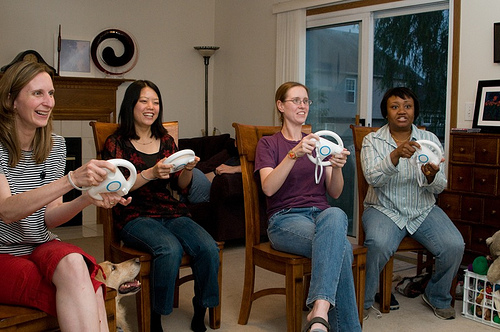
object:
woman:
[2, 59, 111, 332]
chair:
[88, 119, 228, 332]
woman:
[103, 77, 219, 332]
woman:
[256, 81, 363, 332]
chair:
[233, 119, 367, 329]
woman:
[361, 87, 465, 323]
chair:
[350, 121, 432, 312]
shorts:
[0, 238, 104, 314]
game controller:
[84, 159, 137, 201]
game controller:
[164, 149, 197, 173]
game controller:
[306, 128, 343, 183]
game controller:
[407, 137, 441, 168]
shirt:
[0, 132, 67, 254]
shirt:
[361, 122, 447, 235]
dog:
[96, 255, 143, 332]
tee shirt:
[253, 131, 334, 207]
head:
[6, 61, 56, 129]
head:
[124, 80, 163, 126]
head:
[274, 82, 314, 127]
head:
[378, 90, 419, 132]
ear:
[5, 87, 17, 110]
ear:
[276, 100, 285, 113]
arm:
[1, 173, 73, 226]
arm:
[42, 140, 85, 229]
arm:
[103, 147, 152, 192]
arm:
[176, 169, 191, 190]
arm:
[258, 137, 296, 197]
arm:
[324, 166, 344, 200]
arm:
[362, 133, 396, 186]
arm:
[425, 133, 448, 192]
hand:
[68, 158, 116, 186]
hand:
[88, 192, 133, 209]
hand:
[152, 158, 169, 180]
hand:
[184, 156, 201, 170]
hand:
[289, 132, 317, 155]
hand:
[331, 150, 351, 169]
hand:
[394, 142, 418, 157]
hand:
[418, 157, 447, 179]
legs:
[27, 240, 107, 332]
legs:
[169, 211, 221, 315]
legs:
[271, 206, 354, 331]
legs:
[415, 202, 465, 303]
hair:
[2, 60, 54, 167]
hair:
[116, 77, 167, 140]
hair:
[275, 80, 308, 121]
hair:
[379, 87, 421, 124]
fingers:
[92, 158, 116, 172]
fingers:
[119, 195, 132, 206]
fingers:
[158, 157, 168, 163]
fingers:
[196, 156, 200, 162]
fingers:
[305, 140, 316, 147]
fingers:
[340, 150, 350, 155]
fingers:
[407, 140, 421, 149]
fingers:
[429, 162, 440, 171]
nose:
[43, 94, 54, 108]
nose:
[146, 101, 154, 110]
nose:
[299, 101, 306, 109]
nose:
[397, 104, 407, 114]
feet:
[151, 315, 169, 331]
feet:
[304, 309, 330, 332]